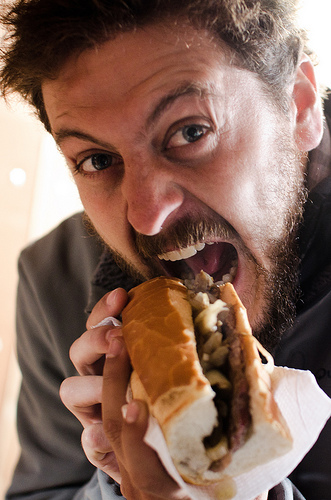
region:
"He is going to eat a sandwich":
[0, 1, 328, 498]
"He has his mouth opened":
[1, 1, 329, 318]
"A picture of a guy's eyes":
[53, 87, 259, 174]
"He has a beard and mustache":
[0, 6, 329, 355]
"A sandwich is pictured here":
[111, 270, 301, 482]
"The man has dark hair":
[1, 0, 329, 345]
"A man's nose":
[109, 136, 189, 241]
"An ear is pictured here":
[282, 59, 329, 154]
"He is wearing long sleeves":
[0, 4, 327, 498]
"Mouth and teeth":
[112, 237, 273, 296]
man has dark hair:
[46, 1, 296, 96]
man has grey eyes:
[168, 109, 213, 147]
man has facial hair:
[256, 114, 304, 320]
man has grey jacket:
[5, 220, 83, 496]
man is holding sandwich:
[96, 282, 289, 473]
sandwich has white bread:
[138, 289, 267, 473]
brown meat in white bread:
[186, 278, 256, 452]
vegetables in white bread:
[173, 286, 238, 428]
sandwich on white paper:
[85, 261, 287, 468]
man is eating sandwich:
[128, 226, 290, 456]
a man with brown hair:
[2, 6, 324, 497]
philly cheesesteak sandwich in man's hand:
[110, 271, 283, 475]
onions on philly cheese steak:
[197, 306, 225, 420]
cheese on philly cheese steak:
[195, 306, 233, 382]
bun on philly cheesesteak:
[133, 296, 186, 393]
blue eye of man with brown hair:
[164, 115, 216, 148]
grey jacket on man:
[56, 247, 97, 297]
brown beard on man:
[119, 217, 301, 315]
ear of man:
[289, 47, 330, 149]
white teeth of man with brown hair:
[152, 237, 230, 262]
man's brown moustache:
[126, 218, 248, 258]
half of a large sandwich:
[115, 271, 291, 485]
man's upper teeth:
[145, 236, 223, 259]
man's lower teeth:
[170, 263, 240, 293]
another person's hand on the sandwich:
[94, 332, 192, 498]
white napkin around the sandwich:
[126, 364, 330, 499]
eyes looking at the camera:
[57, 114, 213, 176]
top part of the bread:
[115, 268, 221, 466]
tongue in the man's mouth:
[181, 236, 226, 276]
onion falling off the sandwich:
[249, 327, 273, 374]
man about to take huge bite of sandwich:
[53, 182, 291, 472]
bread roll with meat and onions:
[152, 352, 284, 479]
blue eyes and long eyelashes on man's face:
[46, 103, 233, 183]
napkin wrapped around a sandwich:
[75, 313, 159, 464]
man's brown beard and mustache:
[58, 217, 299, 351]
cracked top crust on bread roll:
[135, 304, 205, 407]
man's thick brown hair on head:
[7, 7, 88, 96]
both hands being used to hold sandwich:
[61, 331, 211, 496]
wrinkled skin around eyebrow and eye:
[140, 77, 249, 170]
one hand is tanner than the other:
[61, 285, 149, 481]